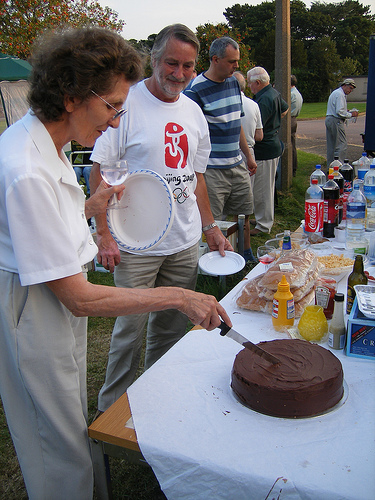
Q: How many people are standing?
A: Seven.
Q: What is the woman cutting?
A: Cake.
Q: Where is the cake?
A: On Table.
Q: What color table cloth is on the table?
A: White.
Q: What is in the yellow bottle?
A: Mustard.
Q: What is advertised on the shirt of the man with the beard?
A: Olympics.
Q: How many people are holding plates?
A: Two.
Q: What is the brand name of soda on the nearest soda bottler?
A: Coca Cola.